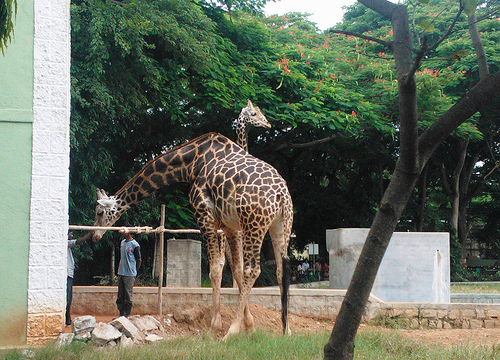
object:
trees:
[70, 0, 169, 276]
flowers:
[282, 62, 293, 75]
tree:
[291, 67, 361, 143]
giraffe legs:
[273, 212, 299, 340]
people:
[298, 255, 307, 278]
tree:
[444, 119, 486, 284]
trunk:
[332, 1, 447, 333]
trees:
[321, 0, 498, 359]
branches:
[328, 27, 395, 52]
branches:
[463, 0, 490, 71]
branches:
[406, 0, 464, 78]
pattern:
[215, 172, 223, 182]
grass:
[12, 322, 499, 357]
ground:
[49, 282, 489, 354]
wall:
[398, 236, 445, 301]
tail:
[278, 211, 296, 330]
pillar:
[156, 208, 170, 335]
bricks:
[167, 242, 201, 289]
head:
[241, 102, 271, 127]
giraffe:
[230, 95, 272, 156]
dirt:
[169, 300, 373, 340]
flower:
[351, 53, 366, 60]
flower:
[342, 79, 372, 94]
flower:
[346, 103, 367, 119]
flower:
[273, 50, 308, 80]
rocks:
[118, 314, 135, 342]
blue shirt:
[115, 237, 141, 275]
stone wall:
[24, 1, 69, 334]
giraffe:
[92, 124, 300, 343]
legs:
[189, 194, 232, 347]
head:
[92, 187, 122, 242]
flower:
[278, 59, 290, 76]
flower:
[377, 50, 384, 60]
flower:
[350, 109, 357, 115]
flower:
[321, 41, 332, 51]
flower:
[333, 72, 337, 80]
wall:
[0, 0, 27, 346]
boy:
[114, 229, 140, 312]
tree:
[215, 7, 434, 249]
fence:
[72, 231, 499, 284]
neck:
[120, 138, 201, 207]